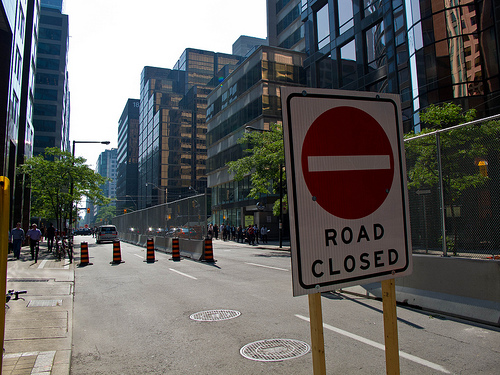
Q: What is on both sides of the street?
A: Tall buildings.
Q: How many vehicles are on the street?
A: One.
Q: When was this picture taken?
A: Daytime.